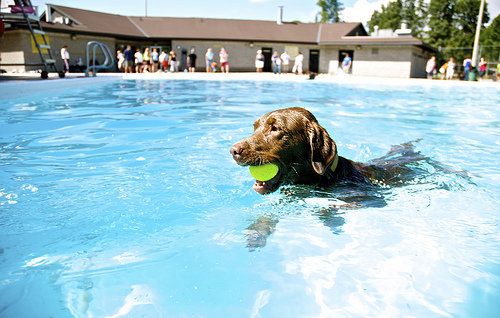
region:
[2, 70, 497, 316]
a clean refreshing public pool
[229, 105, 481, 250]
a large brown dog swimming in the pool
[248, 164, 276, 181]
a bright yellow tennis ball inside the mouth of a brown dog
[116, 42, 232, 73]
a group of people standing around a pool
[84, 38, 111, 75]
hand rails found at the edge of pool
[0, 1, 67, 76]
stairs that lead to the life guard's bench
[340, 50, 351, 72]
a person in a blue shirt standing in a doorway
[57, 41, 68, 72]
a person in a white shirt standing near the pool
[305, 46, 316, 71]
a black door on the pool house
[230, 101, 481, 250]
a happy dog playing in a pool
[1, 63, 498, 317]
large swimming pool filled with clear blue water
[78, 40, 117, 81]
blue metal pool railing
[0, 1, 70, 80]
metal lifeguard chair on wheels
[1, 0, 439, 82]
white building with brown roof by pool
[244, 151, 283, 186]
yellow tennis ball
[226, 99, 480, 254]
brown dog swimming in pool with tennis ball in its mouth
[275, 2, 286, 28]
small metal chimney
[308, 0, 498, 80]
group of green trees near pool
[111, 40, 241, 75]
people standing near a large pool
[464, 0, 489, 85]
pole near large pool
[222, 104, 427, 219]
brown dog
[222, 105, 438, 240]
brown dog swimming in pool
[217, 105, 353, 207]
brown dog with yellow ball in mouth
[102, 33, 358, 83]
people standing on side of pool in background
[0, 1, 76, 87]
ladder to life guard chair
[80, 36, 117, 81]
railing for climbing out of pool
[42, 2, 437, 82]
large building in background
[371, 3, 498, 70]
green trees in background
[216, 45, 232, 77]
person wearing red shorts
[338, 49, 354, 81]
person wearing blue shirt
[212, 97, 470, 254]
medium sized brown dog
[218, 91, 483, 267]
brown dog holding tennis ball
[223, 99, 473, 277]
brown dog swimming in a pool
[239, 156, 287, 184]
small yellow tennis ball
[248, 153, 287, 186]
small ball in dog's mouth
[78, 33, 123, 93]
ladder to the pool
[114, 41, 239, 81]
crowd of people outside poolhouse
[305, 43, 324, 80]
door to building behind pool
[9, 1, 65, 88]
ladder outside swimming pool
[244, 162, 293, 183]
yellow fetching toy for dog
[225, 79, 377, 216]
this is a dog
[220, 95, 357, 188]
the dog is swimming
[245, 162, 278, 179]
this is a ball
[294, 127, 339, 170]
the ear is folded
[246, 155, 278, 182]
the ball is on the mouth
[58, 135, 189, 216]
the water is blue in color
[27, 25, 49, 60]
this is a staircase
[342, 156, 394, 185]
the dog is wet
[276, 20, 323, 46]
this is a house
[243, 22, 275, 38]
the roof is brown in color